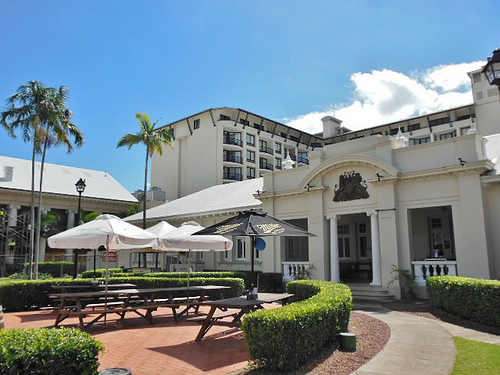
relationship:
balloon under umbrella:
[253, 237, 267, 250] [194, 207, 320, 294]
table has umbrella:
[199, 288, 292, 348] [194, 207, 320, 294]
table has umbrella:
[51, 283, 183, 328] [46, 209, 149, 292]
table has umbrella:
[153, 277, 230, 320] [157, 216, 230, 288]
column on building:
[366, 210, 381, 284] [143, 52, 499, 304]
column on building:
[326, 216, 341, 286] [143, 52, 499, 304]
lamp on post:
[74, 179, 84, 194] [72, 193, 83, 278]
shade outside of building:
[14, 270, 294, 370] [120, 70, 499, 303]